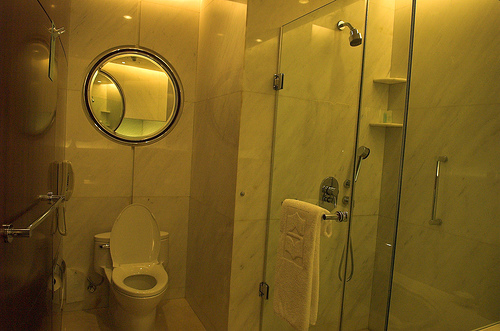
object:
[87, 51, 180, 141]
mirror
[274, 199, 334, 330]
towel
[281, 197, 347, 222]
rack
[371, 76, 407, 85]
shelf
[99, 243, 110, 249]
handle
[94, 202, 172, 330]
toilet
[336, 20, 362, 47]
shower head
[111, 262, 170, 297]
seat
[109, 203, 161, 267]
lid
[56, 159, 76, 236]
telephone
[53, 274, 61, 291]
toilet paper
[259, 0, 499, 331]
shower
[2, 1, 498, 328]
bathroom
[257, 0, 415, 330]
doors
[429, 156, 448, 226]
safety bar